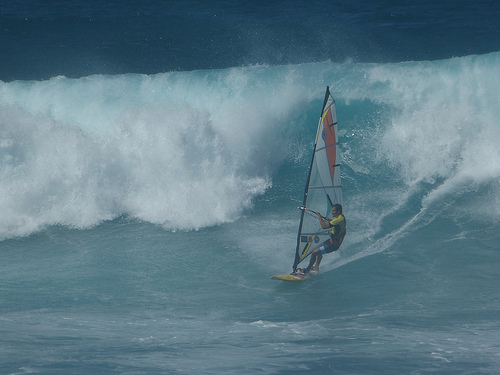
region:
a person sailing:
[276, 68, 372, 289]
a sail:
[289, 78, 354, 293]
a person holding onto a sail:
[281, 193, 369, 283]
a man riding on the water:
[299, 191, 361, 282]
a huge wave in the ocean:
[11, 35, 493, 229]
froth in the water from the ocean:
[8, 77, 234, 269]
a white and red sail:
[289, 81, 369, 270]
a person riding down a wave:
[88, 1, 466, 286]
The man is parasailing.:
[270, 84, 349, 283]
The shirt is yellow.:
[331, 217, 345, 232]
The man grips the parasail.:
[312, 212, 331, 228]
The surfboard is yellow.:
[270, 271, 298, 285]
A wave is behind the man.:
[0, 65, 292, 240]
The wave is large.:
[2, 62, 283, 237]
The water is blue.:
[0, 14, 212, 63]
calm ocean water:
[1, 240, 242, 373]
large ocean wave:
[1, 71, 226, 216]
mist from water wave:
[240, 15, 392, 61]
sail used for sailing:
[315, 95, 347, 207]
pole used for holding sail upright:
[290, 85, 331, 267]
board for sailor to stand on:
[272, 266, 326, 280]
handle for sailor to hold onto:
[301, 201, 330, 224]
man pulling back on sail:
[296, 203, 348, 275]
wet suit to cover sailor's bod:
[312, 214, 347, 254]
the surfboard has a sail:
[274, 95, 356, 287]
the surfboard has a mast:
[281, 82, 346, 287]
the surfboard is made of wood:
[272, 266, 319, 278]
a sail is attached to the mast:
[292, 88, 347, 261]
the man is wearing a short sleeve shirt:
[326, 213, 347, 248]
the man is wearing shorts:
[319, 235, 341, 254]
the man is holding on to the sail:
[300, 203, 341, 228]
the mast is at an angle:
[286, 85, 359, 273]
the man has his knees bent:
[303, 235, 340, 278]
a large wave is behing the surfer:
[6, 58, 493, 252]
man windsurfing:
[276, 80, 362, 297]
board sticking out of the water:
[270, 269, 311, 283]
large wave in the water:
[1, 59, 498, 323]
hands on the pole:
[309, 204, 331, 233]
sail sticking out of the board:
[272, 84, 347, 287]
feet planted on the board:
[290, 261, 322, 276]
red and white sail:
[297, 88, 357, 272]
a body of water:
[1, 0, 497, 374]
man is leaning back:
[289, 185, 355, 277]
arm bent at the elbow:
[311, 209, 333, 234]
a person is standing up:
[298, 202, 349, 278]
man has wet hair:
[329, 197, 347, 213]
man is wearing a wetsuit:
[316, 208, 349, 269]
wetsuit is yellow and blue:
[300, 205, 380, 251]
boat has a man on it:
[266, 88, 376, 289]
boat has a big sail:
[269, 74, 364, 264]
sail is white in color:
[270, 88, 390, 263]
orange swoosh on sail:
[320, 96, 342, 184]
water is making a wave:
[43, 70, 498, 241]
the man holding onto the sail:
[272, 85, 347, 280]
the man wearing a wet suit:
[296, 204, 346, 278]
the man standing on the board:
[273, 203, 346, 283]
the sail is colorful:
[294, 84, 342, 278]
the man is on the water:
[0, 0, 499, 373]